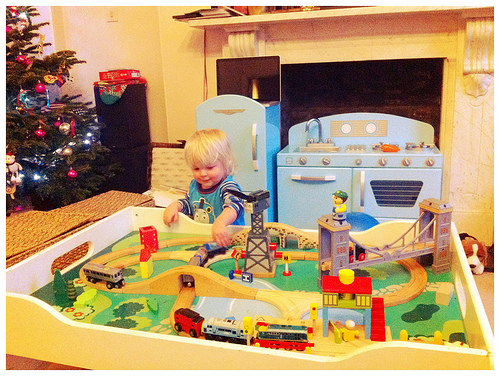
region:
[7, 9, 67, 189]
Christmas tree decorated with lights and ornaments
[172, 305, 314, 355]
toy train with three cars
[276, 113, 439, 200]
toy kitchen sink and stove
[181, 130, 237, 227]
little boy with a blue train shirt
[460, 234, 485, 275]
stuffed dog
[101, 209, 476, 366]
toy train table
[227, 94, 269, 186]
toy refrigerator behind the little boy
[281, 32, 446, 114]
fireplace with a white mantle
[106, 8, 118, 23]
light switch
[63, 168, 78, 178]
red ball Christmas ornament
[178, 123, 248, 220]
this is a baby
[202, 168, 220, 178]
the baby is light skinned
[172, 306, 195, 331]
this is a toy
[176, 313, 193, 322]
the toy is red in color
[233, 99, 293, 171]
this is a chiar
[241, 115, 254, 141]
the chair is white in color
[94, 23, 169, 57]
this is the wall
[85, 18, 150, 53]
the wall is white in color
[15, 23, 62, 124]
this is a tree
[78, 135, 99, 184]
the leaves are green in color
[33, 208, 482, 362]
A toy train table.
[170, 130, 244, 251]
A boy playing with a train.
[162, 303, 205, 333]
A red wooden caboose.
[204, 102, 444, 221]
A blue toy kitchen.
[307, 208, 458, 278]
A wooden toy bridge.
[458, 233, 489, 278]
A stuffed toy dog.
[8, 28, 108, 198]
A decorated Christmas tree.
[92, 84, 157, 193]
A black speaker.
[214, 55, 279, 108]
A black computer monitor.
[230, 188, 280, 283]
A wooden toy crane.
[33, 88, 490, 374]
A small child playing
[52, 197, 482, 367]
A childs train layout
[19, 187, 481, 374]
Train layout with wooden sides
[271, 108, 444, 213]
A toy kitchen sink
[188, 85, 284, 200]
A toy refigerator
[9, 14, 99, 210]
A christmas tree on left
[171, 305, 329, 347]
A toy train on track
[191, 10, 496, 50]
A fireplace mantel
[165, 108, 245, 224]
A small child with blonde hair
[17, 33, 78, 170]
Christmas tree decorations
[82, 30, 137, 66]
this is a wall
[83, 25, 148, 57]
the wall is white in color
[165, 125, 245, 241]
this is a child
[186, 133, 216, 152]
the hair is blonde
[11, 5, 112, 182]
this is a tree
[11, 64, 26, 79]
the leaves are green in color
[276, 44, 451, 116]
this is the fire place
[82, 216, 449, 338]
these are some toys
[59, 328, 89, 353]
the area is wooden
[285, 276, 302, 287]
the area is green in color